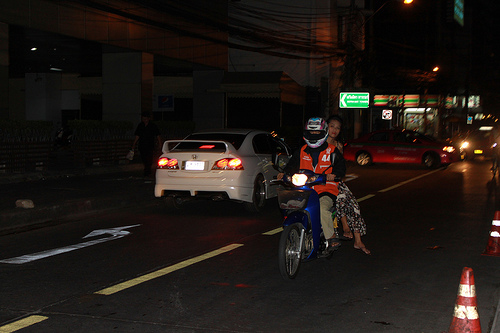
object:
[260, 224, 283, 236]
line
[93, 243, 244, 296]
line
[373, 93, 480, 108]
sign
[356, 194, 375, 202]
line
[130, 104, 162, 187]
person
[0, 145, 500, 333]
road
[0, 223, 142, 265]
arrow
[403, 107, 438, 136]
sign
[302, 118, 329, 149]
helmet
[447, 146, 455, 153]
headlights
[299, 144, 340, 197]
vest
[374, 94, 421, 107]
sign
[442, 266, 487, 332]
cone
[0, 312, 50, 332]
yellow line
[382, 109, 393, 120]
sign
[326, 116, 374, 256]
passenger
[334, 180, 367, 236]
skirt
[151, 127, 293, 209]
car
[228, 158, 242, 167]
lights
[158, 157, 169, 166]
lights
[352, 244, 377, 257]
sandals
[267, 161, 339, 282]
bike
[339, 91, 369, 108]
green sign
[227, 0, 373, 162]
green building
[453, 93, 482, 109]
sign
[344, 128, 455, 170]
car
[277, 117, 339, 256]
driver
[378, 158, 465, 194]
intersection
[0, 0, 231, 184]
building